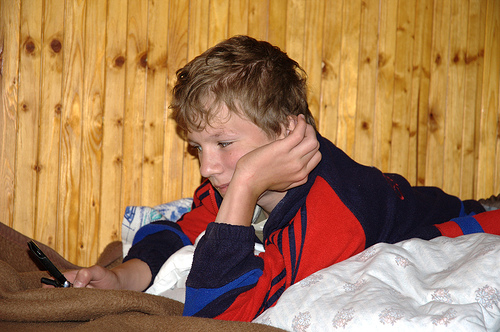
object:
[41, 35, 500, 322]
boy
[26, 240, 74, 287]
phone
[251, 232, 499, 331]
bed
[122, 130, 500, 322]
sweater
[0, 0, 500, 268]
wall